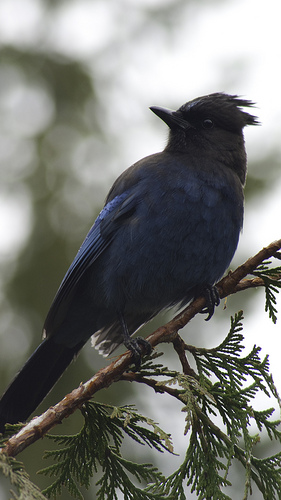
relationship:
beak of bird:
[146, 101, 179, 127] [0, 92, 262, 434]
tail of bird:
[0, 333, 75, 435] [135, 90, 240, 224]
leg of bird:
[117, 307, 154, 367] [0, 92, 262, 434]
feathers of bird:
[162, 171, 225, 225] [0, 92, 262, 434]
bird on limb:
[0, 92, 262, 434] [31, 245, 275, 434]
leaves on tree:
[53, 411, 152, 495] [1, 227, 279, 471]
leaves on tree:
[168, 363, 280, 498] [1, 238, 279, 498]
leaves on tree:
[166, 322, 280, 498] [1, 227, 279, 471]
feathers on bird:
[162, 171, 225, 225] [0, 92, 262, 434]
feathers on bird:
[162, 171, 225, 225] [28, 65, 270, 371]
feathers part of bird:
[162, 171, 225, 225] [0, 92, 262, 434]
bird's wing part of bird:
[62, 217, 115, 273] [0, 92, 262, 434]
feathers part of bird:
[162, 171, 225, 211] [34, 82, 236, 384]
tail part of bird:
[0, 330, 81, 419] [34, 82, 236, 384]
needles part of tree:
[106, 400, 173, 456] [1, 238, 279, 498]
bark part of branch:
[90, 371, 123, 386] [34, 234, 280, 462]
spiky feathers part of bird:
[191, 78, 244, 132] [0, 92, 262, 434]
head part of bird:
[149, 92, 261, 188] [0, 92, 262, 434]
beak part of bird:
[147, 104, 174, 131] [28, 65, 270, 371]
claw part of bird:
[194, 287, 220, 319] [0, 92, 262, 434]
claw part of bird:
[122, 332, 153, 367] [0, 92, 262, 434]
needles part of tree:
[112, 404, 173, 456] [1, 238, 279, 498]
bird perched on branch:
[118, 92, 235, 247] [211, 269, 256, 308]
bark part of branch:
[65, 391, 78, 406] [4, 240, 278, 453]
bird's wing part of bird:
[39, 176, 155, 339] [0, 92, 262, 434]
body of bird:
[107, 156, 244, 317] [32, 77, 278, 359]